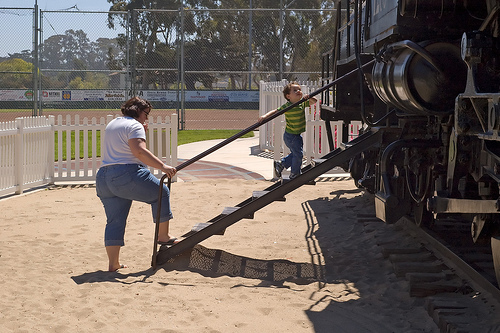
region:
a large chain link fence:
[12, 7, 314, 131]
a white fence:
[1, 110, 174, 197]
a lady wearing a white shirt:
[89, 105, 170, 245]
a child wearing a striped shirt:
[276, 85, 304, 185]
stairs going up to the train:
[161, 101, 381, 275]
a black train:
[331, 15, 498, 192]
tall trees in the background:
[113, 5, 339, 71]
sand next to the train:
[17, 185, 383, 331]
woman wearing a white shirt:
[93, 105, 154, 170]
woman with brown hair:
[116, 89, 158, 131]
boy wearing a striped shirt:
[274, 95, 309, 135]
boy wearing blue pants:
[279, 123, 308, 166]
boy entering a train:
[255, 69, 325, 180]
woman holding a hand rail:
[62, 83, 199, 285]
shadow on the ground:
[224, 240, 349, 291]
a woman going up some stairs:
[48, 104, 200, 279]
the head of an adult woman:
[115, 92, 149, 124]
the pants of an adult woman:
[89, 164, 179, 236]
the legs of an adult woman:
[81, 158, 171, 275]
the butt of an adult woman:
[72, 160, 142, 192]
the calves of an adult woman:
[100, 214, 175, 261]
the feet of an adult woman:
[93, 254, 183, 273]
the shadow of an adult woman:
[66, 261, 153, 288]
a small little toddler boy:
[263, 53, 332, 181]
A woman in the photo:
[67, 77, 182, 266]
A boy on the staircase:
[255, 65, 305, 165]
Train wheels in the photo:
[395, 127, 495, 251]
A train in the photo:
[389, 38, 497, 168]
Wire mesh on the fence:
[162, 29, 275, 67]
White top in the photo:
[101, 113, 143, 161]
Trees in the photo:
[156, 28, 276, 71]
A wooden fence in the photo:
[27, 128, 74, 178]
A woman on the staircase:
[98, 102, 172, 258]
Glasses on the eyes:
[142, 108, 157, 117]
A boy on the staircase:
[272, 72, 322, 154]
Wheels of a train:
[403, 169, 494, 255]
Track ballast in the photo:
[405, 236, 466, 320]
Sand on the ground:
[24, 254, 89, 318]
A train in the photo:
[389, 42, 496, 135]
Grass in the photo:
[186, 122, 230, 148]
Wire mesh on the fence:
[180, 5, 252, 62]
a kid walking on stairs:
[151, 48, 402, 265]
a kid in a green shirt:
[258, 81, 318, 178]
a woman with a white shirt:
[87, 97, 181, 272]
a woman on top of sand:
[0, 95, 499, 331]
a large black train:
[319, 0, 498, 284]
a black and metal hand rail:
[148, 54, 387, 267]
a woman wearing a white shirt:
[101, 112, 155, 162]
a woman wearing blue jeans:
[92, 160, 165, 245]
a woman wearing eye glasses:
[138, 100, 154, 119]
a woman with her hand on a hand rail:
[148, 154, 193, 188]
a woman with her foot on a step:
[149, 175, 181, 251]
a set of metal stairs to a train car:
[167, 57, 371, 267]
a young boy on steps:
[273, 77, 305, 184]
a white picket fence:
[6, 110, 86, 197]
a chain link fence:
[147, 6, 255, 118]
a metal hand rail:
[161, 56, 374, 236]